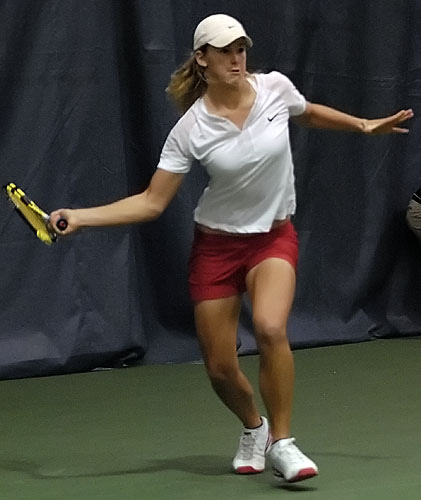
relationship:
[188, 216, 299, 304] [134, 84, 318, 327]
shorts of player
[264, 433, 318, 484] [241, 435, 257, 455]
foot has white laces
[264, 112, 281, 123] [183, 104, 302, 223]
logo on a shirt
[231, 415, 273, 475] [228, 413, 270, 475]
foot on foot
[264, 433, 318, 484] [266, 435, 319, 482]
foot on foot